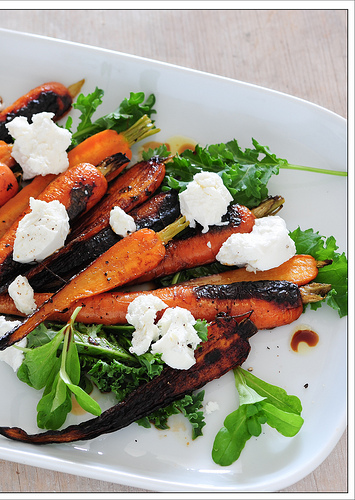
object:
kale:
[26, 318, 208, 440]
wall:
[291, 116, 335, 144]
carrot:
[0, 78, 86, 144]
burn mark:
[193, 281, 307, 293]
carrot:
[0, 282, 330, 328]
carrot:
[128, 195, 284, 284]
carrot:
[0, 318, 258, 443]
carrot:
[171, 253, 332, 287]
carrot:
[0, 162, 108, 275]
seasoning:
[81, 294, 249, 311]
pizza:
[161, 136, 280, 193]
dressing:
[291, 329, 319, 351]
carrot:
[0, 138, 16, 167]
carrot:
[0, 114, 160, 239]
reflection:
[197, 464, 238, 478]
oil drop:
[291, 329, 319, 353]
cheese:
[178, 171, 234, 234]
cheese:
[125, 293, 169, 355]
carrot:
[23, 187, 184, 294]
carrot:
[0, 162, 19, 207]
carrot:
[23, 159, 164, 280]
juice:
[290, 329, 318, 351]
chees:
[192, 166, 273, 250]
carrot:
[0, 214, 190, 351]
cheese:
[151, 306, 202, 371]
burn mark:
[67, 180, 95, 220]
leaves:
[139, 142, 170, 165]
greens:
[161, 136, 347, 206]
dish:
[0, 26, 349, 496]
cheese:
[13, 195, 69, 263]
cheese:
[8, 274, 38, 314]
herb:
[211, 367, 303, 466]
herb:
[17, 307, 102, 431]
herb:
[288, 226, 348, 317]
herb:
[59, 87, 155, 153]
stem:
[120, 114, 161, 149]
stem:
[160, 212, 187, 244]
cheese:
[214, 215, 296, 275]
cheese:
[109, 205, 136, 238]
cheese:
[5, 111, 72, 180]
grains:
[100, 258, 121, 321]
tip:
[2, 424, 60, 449]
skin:
[0, 277, 304, 326]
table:
[1, 9, 350, 491]